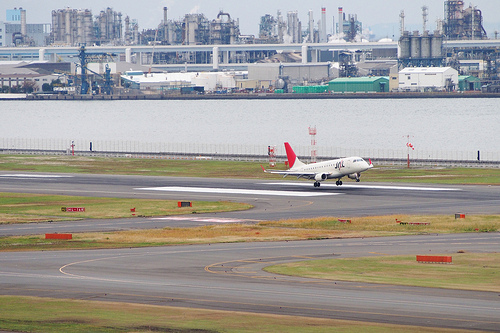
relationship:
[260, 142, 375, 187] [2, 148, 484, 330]
airplane at an airport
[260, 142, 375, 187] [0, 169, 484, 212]
airplane going down runway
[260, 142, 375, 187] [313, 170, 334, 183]
airplane has engines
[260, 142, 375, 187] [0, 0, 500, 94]
airplane close to a building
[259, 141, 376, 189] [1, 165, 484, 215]
airplane driving on a runway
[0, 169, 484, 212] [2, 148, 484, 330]
runway at an airport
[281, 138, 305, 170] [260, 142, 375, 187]
fin on a airplane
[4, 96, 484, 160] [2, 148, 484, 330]
river between airport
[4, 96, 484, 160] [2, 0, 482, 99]
river between buildings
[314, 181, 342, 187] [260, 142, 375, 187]
landing gear on airplane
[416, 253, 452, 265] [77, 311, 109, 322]
mmarker in grass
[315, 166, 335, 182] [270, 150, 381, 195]
engine on plane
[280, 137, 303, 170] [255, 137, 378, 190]
tail fin on plane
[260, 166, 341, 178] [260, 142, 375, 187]
wing on airplane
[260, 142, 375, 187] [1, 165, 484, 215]
airplane on runway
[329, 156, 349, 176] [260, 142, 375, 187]
logo on airplane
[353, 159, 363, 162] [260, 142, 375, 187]
windows on airplane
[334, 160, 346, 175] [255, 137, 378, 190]
door on plane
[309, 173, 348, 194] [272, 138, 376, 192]
landing gear on plane